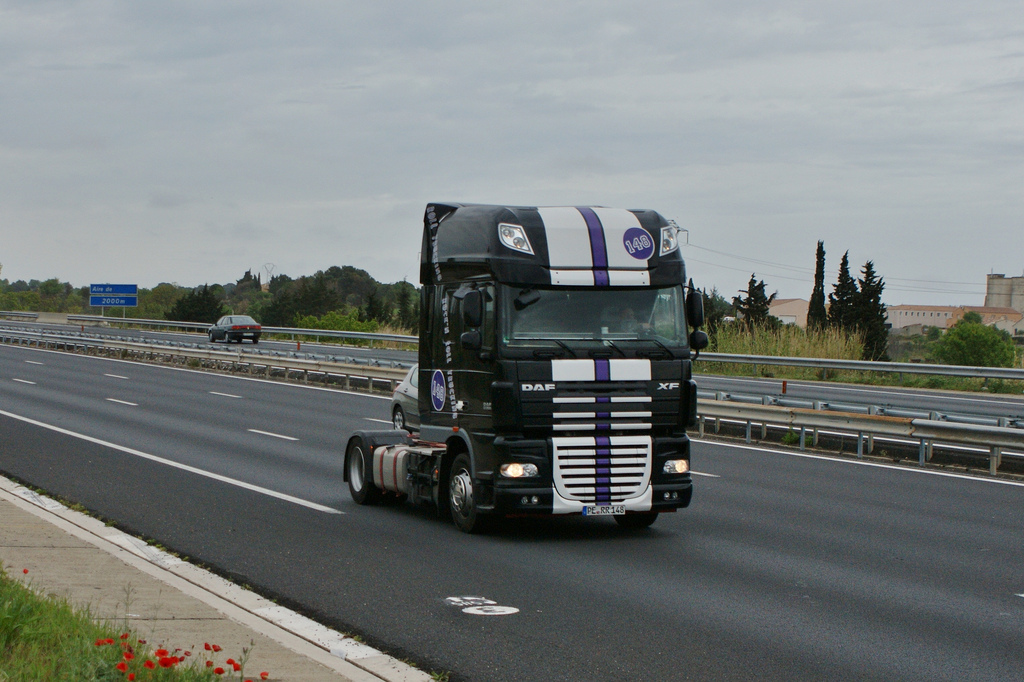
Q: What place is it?
A: It is a highway.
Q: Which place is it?
A: It is a highway.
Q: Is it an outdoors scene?
A: Yes, it is outdoors.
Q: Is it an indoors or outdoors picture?
A: It is outdoors.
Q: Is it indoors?
A: No, it is outdoors.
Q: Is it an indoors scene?
A: No, it is outdoors.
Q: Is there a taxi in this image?
A: Yes, there is a taxi.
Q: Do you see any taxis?
A: Yes, there is a taxi.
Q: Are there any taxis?
A: Yes, there is a taxi.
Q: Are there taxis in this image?
A: Yes, there is a taxi.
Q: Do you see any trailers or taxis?
A: Yes, there is a taxi.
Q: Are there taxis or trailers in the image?
A: Yes, there is a taxi.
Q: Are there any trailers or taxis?
A: Yes, there is a taxi.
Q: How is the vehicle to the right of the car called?
A: The vehicle is a taxi.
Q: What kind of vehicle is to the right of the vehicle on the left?
A: The vehicle is a taxi.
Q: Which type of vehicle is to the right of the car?
A: The vehicle is a taxi.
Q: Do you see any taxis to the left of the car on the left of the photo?
A: No, the taxi is to the right of the car.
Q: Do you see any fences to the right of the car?
A: No, there is a taxi to the right of the car.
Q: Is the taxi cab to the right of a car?
A: Yes, the taxi cab is to the right of a car.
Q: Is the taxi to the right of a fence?
A: No, the taxi is to the right of a car.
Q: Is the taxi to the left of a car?
A: No, the taxi is to the right of a car.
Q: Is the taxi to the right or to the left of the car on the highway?
A: The taxi is to the right of the car.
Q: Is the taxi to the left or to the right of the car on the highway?
A: The taxi is to the right of the car.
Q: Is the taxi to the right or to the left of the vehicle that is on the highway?
A: The taxi is to the right of the car.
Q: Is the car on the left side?
A: Yes, the car is on the left of the image.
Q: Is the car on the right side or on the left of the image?
A: The car is on the left of the image.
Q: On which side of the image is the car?
A: The car is on the left of the image.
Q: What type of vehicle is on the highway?
A: The vehicle is a car.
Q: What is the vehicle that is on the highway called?
A: The vehicle is a car.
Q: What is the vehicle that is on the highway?
A: The vehicle is a car.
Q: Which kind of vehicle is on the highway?
A: The vehicle is a car.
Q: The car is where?
A: The car is on the highway.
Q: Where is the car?
A: The car is on the highway.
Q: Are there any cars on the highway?
A: Yes, there is a car on the highway.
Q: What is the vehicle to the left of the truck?
A: The vehicle is a car.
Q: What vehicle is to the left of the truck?
A: The vehicle is a car.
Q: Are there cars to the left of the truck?
A: Yes, there is a car to the left of the truck.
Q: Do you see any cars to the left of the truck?
A: Yes, there is a car to the left of the truck.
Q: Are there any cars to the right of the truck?
A: No, the car is to the left of the truck.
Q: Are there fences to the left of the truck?
A: No, there is a car to the left of the truck.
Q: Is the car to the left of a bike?
A: No, the car is to the left of the truck.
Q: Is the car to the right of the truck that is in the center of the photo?
A: No, the car is to the left of the truck.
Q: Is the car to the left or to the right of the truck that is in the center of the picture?
A: The car is to the left of the truck.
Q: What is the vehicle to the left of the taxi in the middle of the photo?
A: The vehicle is a car.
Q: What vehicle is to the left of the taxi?
A: The vehicle is a car.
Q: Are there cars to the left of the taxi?
A: Yes, there is a car to the left of the taxi.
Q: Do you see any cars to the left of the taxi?
A: Yes, there is a car to the left of the taxi.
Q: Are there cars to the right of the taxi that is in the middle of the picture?
A: No, the car is to the left of the taxi.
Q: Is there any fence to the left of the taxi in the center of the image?
A: No, there is a car to the left of the cab.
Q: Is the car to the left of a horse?
A: No, the car is to the left of a taxi.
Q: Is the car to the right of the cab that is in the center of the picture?
A: No, the car is to the left of the taxi.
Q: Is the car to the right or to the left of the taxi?
A: The car is to the left of the taxi.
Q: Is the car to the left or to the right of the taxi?
A: The car is to the left of the taxi.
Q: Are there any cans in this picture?
A: No, there are no cans.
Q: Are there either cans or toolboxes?
A: No, there are no cans or toolboxes.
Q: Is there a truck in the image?
A: Yes, there is a truck.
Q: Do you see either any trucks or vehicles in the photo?
A: Yes, there is a truck.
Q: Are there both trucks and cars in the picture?
A: Yes, there are both a truck and cars.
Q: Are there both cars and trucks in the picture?
A: Yes, there are both a truck and cars.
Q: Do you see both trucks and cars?
A: Yes, there are both a truck and cars.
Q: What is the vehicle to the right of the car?
A: The vehicle is a truck.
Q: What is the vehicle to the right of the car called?
A: The vehicle is a truck.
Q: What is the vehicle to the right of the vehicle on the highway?
A: The vehicle is a truck.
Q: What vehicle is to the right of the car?
A: The vehicle is a truck.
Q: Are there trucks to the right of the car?
A: Yes, there is a truck to the right of the car.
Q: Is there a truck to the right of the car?
A: Yes, there is a truck to the right of the car.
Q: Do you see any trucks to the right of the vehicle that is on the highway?
A: Yes, there is a truck to the right of the car.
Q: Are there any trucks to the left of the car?
A: No, the truck is to the right of the car.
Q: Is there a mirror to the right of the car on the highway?
A: No, there is a truck to the right of the car.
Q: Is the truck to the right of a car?
A: Yes, the truck is to the right of a car.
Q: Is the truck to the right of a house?
A: No, the truck is to the right of a car.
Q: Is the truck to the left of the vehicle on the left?
A: No, the truck is to the right of the car.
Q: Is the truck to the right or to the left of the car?
A: The truck is to the right of the car.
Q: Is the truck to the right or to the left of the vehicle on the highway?
A: The truck is to the right of the car.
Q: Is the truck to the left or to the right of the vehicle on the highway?
A: The truck is to the right of the car.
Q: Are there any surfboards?
A: No, there are no surfboards.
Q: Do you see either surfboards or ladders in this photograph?
A: No, there are no surfboards or ladders.